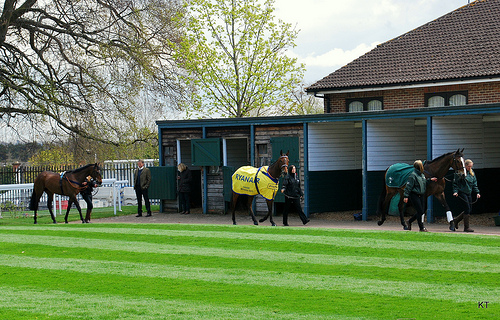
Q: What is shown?
A: People walking horses.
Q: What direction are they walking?
A: To the right.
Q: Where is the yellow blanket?
A: On the center horse.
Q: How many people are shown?
A: Six.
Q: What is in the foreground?
A: Grass.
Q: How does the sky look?
A: Cloudy.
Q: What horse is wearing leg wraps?
A: The front horse.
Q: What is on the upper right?
A: A building.